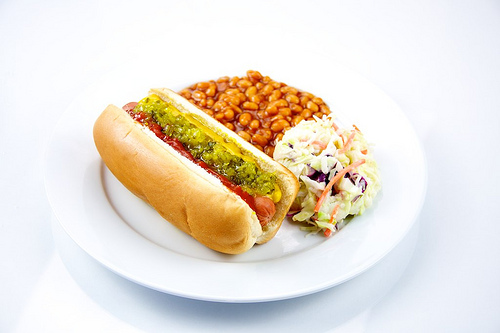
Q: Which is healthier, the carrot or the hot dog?
A: The carrot is healthier than the hot dog.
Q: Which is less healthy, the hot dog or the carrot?
A: The hot dog is less healthy than the carrot.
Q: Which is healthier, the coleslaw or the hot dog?
A: The coleslaw is healthier than the hot dog.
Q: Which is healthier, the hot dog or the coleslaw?
A: The coleslaw is healthier than the hot dog.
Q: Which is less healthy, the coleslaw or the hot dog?
A: The hot dog is less healthy than the coleslaw.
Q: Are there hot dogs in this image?
A: Yes, there is a hot dog.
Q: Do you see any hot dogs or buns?
A: Yes, there is a hot dog.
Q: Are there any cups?
A: No, there are no cups.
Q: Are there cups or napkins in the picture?
A: No, there are no cups or napkins.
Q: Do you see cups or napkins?
A: No, there are no cups or napkins.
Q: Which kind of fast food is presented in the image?
A: The fast food is a hot dog.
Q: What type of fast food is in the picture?
A: The fast food is a hot dog.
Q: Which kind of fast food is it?
A: The food is a hot dog.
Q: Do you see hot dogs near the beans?
A: Yes, there is a hot dog near the beans.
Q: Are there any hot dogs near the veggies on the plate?
A: Yes, there is a hot dog near the beans.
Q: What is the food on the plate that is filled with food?
A: The food is a hot dog.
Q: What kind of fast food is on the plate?
A: The food is a hot dog.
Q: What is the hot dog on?
A: The hot dog is on the plate.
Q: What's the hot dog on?
A: The hot dog is on the plate.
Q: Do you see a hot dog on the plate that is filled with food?
A: Yes, there is a hot dog on the plate.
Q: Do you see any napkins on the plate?
A: No, there is a hot dog on the plate.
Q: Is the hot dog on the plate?
A: Yes, the hot dog is on the plate.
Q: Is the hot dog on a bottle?
A: No, the hot dog is on the plate.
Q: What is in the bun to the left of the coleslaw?
A: The hot dog is in the bun.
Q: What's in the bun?
A: The hot dog is in the bun.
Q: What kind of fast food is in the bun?
A: The food is a hot dog.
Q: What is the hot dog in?
A: The hot dog is in the bun.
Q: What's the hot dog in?
A: The hot dog is in the bun.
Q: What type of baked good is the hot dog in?
A: The hot dog is in the bun.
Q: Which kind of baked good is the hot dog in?
A: The hot dog is in the bun.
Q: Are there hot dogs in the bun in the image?
A: Yes, there is a hot dog in the bun.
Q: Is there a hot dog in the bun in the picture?
A: Yes, there is a hot dog in the bun.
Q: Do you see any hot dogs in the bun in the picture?
A: Yes, there is a hot dog in the bun.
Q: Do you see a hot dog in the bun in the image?
A: Yes, there is a hot dog in the bun.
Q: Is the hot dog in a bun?
A: Yes, the hot dog is in a bun.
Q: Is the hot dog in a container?
A: No, the hot dog is in a bun.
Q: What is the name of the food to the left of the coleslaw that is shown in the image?
A: The food is a hot dog.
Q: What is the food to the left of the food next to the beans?
A: The food is a hot dog.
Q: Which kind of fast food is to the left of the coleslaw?
A: The food is a hot dog.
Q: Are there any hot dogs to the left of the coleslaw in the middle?
A: Yes, there is a hot dog to the left of the coleslaw.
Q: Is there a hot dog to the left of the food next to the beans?
A: Yes, there is a hot dog to the left of the coleslaw.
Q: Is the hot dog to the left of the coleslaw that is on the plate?
A: Yes, the hot dog is to the left of the coleslaw.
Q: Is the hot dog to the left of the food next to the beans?
A: Yes, the hot dog is to the left of the coleslaw.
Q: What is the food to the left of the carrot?
A: The food is a hot dog.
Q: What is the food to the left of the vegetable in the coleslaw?
A: The food is a hot dog.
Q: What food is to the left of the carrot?
A: The food is a hot dog.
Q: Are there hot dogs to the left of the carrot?
A: Yes, there is a hot dog to the left of the carrot.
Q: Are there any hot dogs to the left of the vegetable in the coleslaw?
A: Yes, there is a hot dog to the left of the carrot.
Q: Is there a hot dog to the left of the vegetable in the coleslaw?
A: Yes, there is a hot dog to the left of the carrot.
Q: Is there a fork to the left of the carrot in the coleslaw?
A: No, there is a hot dog to the left of the carrot.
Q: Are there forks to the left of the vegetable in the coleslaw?
A: No, there is a hot dog to the left of the carrot.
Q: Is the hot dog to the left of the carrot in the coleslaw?
A: Yes, the hot dog is to the left of the carrot.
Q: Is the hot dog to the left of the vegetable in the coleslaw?
A: Yes, the hot dog is to the left of the carrot.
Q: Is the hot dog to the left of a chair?
A: No, the hot dog is to the left of the carrot.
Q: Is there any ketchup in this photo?
A: Yes, there is ketchup.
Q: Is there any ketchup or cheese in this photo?
A: Yes, there is ketchup.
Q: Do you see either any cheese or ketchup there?
A: Yes, there is ketchup.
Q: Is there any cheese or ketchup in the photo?
A: Yes, there is ketchup.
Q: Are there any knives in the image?
A: No, there are no knives.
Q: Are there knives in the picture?
A: No, there are no knives.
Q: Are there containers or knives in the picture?
A: No, there are no knives or containers.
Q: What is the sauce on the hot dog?
A: The sauce is ketchup.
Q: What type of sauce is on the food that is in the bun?
A: The sauce is ketchup.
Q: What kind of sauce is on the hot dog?
A: The sauce is ketchup.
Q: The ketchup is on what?
A: The ketchup is on the hot dog.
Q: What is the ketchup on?
A: The ketchup is on the hot dog.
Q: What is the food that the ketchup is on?
A: The food is a hot dog.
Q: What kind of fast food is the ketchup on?
A: The ketchup is on the hot dog.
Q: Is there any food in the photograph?
A: Yes, there is food.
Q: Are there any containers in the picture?
A: No, there are no containers.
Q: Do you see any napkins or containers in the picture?
A: No, there are no containers or napkins.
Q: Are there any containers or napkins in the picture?
A: No, there are no containers or napkins.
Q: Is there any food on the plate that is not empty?
A: Yes, there is food on the plate.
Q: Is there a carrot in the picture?
A: Yes, there is a carrot.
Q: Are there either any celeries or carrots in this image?
A: Yes, there is a carrot.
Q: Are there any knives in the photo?
A: No, there are no knives.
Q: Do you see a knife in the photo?
A: No, there are no knives.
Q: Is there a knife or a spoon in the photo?
A: No, there are no knives or spoons.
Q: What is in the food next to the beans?
A: The carrot is in the coleslaw.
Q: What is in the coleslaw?
A: The carrot is in the coleslaw.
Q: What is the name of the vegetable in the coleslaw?
A: The vegetable is a carrot.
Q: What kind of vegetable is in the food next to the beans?
A: The vegetable is a carrot.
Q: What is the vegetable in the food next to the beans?
A: The vegetable is a carrot.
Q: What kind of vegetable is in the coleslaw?
A: The vegetable is a carrot.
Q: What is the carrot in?
A: The carrot is in the coleslaw.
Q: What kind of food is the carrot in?
A: The carrot is in the coleslaw.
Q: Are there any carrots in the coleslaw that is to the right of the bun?
A: Yes, there is a carrot in the coleslaw.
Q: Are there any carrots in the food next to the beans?
A: Yes, there is a carrot in the coleslaw.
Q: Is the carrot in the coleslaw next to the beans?
A: Yes, the carrot is in the coleslaw.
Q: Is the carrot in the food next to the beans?
A: Yes, the carrot is in the coleslaw.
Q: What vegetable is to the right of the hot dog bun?
A: The vegetable is a carrot.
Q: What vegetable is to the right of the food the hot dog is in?
A: The vegetable is a carrot.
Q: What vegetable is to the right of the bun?
A: The vegetable is a carrot.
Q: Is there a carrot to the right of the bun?
A: Yes, there is a carrot to the right of the bun.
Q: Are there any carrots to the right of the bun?
A: Yes, there is a carrot to the right of the bun.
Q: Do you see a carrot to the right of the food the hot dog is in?
A: Yes, there is a carrot to the right of the bun.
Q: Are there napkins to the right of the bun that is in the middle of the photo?
A: No, there is a carrot to the right of the bun.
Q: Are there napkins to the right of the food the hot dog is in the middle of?
A: No, there is a carrot to the right of the bun.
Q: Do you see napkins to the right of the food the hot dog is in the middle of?
A: No, there is a carrot to the right of the bun.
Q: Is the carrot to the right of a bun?
A: Yes, the carrot is to the right of a bun.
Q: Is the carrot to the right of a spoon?
A: No, the carrot is to the right of a bun.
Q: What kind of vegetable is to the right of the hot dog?
A: The vegetable is a carrot.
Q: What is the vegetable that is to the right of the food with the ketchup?
A: The vegetable is a carrot.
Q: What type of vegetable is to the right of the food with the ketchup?
A: The vegetable is a carrot.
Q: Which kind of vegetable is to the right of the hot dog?
A: The vegetable is a carrot.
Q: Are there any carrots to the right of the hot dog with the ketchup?
A: Yes, there is a carrot to the right of the hot dog.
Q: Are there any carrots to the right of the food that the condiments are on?
A: Yes, there is a carrot to the right of the hot dog.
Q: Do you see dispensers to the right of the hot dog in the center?
A: No, there is a carrot to the right of the hot dog.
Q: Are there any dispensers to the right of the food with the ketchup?
A: No, there is a carrot to the right of the hot dog.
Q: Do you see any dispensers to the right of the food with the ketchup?
A: No, there is a carrot to the right of the hot dog.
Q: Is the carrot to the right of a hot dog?
A: Yes, the carrot is to the right of a hot dog.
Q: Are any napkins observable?
A: No, there are no napkins.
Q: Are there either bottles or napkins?
A: No, there are no napkins or bottles.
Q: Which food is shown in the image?
A: The food is a bun.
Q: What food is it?
A: The food is a bun.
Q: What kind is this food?
A: This is a bun.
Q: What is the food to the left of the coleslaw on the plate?
A: The food is a bun.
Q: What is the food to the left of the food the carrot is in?
A: The food is a bun.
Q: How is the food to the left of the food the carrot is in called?
A: The food is a bun.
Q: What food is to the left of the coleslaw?
A: The food is a bun.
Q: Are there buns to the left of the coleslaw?
A: Yes, there is a bun to the left of the coleslaw.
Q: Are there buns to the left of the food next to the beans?
A: Yes, there is a bun to the left of the coleslaw.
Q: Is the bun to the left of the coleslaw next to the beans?
A: Yes, the bun is to the left of the coleslaw.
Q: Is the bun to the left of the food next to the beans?
A: Yes, the bun is to the left of the coleslaw.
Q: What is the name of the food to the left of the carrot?
A: The food is a bun.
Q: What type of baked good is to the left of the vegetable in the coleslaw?
A: The food is a bun.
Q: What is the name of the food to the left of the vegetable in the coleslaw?
A: The food is a bun.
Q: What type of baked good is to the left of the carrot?
A: The food is a bun.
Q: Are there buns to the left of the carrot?
A: Yes, there is a bun to the left of the carrot.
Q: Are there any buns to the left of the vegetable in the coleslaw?
A: Yes, there is a bun to the left of the carrot.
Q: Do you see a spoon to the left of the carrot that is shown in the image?
A: No, there is a bun to the left of the carrot.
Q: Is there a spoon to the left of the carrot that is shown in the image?
A: No, there is a bun to the left of the carrot.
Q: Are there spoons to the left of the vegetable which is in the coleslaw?
A: No, there is a bun to the left of the carrot.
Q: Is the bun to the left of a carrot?
A: Yes, the bun is to the left of a carrot.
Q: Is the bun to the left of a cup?
A: No, the bun is to the left of a carrot.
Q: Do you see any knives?
A: No, there are no knives.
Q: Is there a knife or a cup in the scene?
A: No, there are no knives or cups.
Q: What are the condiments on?
A: The condiments are on the hot dog.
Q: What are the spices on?
A: The condiments are on the hot dog.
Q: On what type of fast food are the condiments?
A: The condiments are on the hot dog.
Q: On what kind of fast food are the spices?
A: The condiments are on the hot dog.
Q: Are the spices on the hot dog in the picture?
A: Yes, the spices are on the hot dog.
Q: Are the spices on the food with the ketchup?
A: Yes, the spices are on the hot dog.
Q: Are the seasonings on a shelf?
A: No, the seasonings are on the hot dog.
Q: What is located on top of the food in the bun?
A: The condiments are on top of the hot dog.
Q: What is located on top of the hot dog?
A: The condiments are on top of the hot dog.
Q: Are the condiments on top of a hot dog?
A: Yes, the condiments are on top of a hot dog.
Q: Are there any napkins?
A: No, there are no napkins.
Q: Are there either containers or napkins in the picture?
A: No, there are no napkins or containers.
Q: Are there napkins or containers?
A: No, there are no napkins or containers.